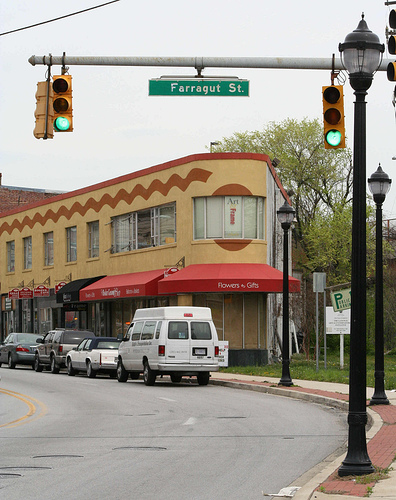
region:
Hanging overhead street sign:
[146, 66, 254, 100]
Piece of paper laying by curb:
[266, 476, 307, 498]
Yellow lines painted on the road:
[1, 385, 49, 433]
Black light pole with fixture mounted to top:
[338, 9, 386, 476]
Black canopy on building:
[54, 277, 82, 304]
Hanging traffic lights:
[32, 51, 75, 146]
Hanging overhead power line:
[1, 1, 125, 50]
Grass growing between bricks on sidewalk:
[315, 474, 390, 498]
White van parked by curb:
[115, 304, 221, 386]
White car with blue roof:
[66, 336, 120, 375]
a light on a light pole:
[340, 13, 382, 450]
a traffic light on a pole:
[33, 49, 82, 145]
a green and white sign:
[144, 74, 252, 102]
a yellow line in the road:
[3, 380, 39, 431]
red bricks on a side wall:
[370, 397, 391, 457]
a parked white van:
[111, 304, 218, 380]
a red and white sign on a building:
[29, 282, 53, 294]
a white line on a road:
[182, 398, 207, 435]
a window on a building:
[193, 193, 265, 247]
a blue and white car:
[67, 336, 113, 377]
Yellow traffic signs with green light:
[22, 71, 78, 147]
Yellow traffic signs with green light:
[305, 78, 350, 166]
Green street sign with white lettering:
[135, 69, 256, 109]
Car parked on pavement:
[115, 291, 255, 410]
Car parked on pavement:
[66, 321, 116, 381]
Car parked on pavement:
[27, 313, 87, 392]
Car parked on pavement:
[0, 329, 37, 394]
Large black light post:
[370, 157, 394, 422]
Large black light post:
[251, 188, 315, 392]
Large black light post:
[324, 33, 393, 499]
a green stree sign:
[148, 66, 304, 111]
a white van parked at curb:
[107, 296, 232, 405]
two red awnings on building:
[79, 259, 308, 312]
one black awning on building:
[50, 267, 99, 309]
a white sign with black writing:
[321, 306, 371, 381]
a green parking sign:
[326, 276, 367, 321]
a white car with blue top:
[61, 322, 131, 392]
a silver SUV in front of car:
[28, 324, 79, 383]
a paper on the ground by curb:
[253, 469, 335, 497]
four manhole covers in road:
[5, 440, 190, 488]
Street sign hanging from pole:
[144, 60, 252, 99]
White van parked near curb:
[116, 305, 218, 381]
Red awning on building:
[155, 261, 309, 300]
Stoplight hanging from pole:
[317, 60, 345, 148]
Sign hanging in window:
[220, 193, 244, 237]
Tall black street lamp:
[268, 198, 303, 391]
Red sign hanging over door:
[32, 274, 51, 300]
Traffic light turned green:
[49, 55, 76, 131]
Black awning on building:
[56, 274, 110, 303]